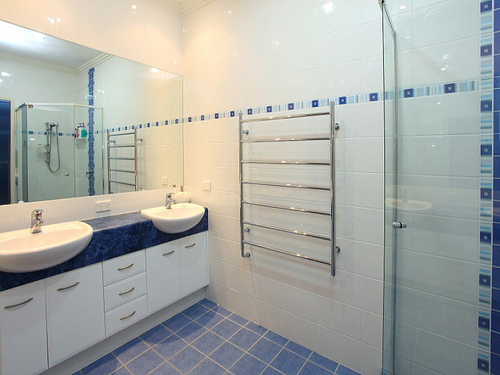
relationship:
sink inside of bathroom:
[142, 201, 205, 232] [1, 0, 498, 375]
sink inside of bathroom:
[1, 221, 94, 272] [1, 0, 498, 375]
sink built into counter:
[0, 221, 94, 272] [1, 204, 209, 296]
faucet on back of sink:
[165, 191, 177, 210] [142, 201, 205, 232]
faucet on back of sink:
[27, 206, 46, 235] [1, 221, 94, 272]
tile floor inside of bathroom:
[67, 297, 375, 374] [1, 0, 498, 375]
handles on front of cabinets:
[4, 241, 196, 320] [1, 231, 208, 374]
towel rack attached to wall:
[235, 100, 341, 278] [183, 0, 499, 373]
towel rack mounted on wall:
[235, 100, 341, 278] [183, 0, 499, 373]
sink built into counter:
[142, 201, 205, 232] [1, 204, 209, 296]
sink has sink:
[142, 201, 205, 232] [137, 201, 204, 232]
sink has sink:
[1, 221, 94, 272] [0, 221, 94, 272]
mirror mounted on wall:
[0, 20, 184, 208] [0, 0, 182, 81]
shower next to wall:
[379, 1, 498, 374] [183, 0, 499, 373]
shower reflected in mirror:
[379, 1, 498, 374] [0, 20, 184, 208]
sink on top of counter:
[0, 221, 94, 272] [1, 204, 209, 296]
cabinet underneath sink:
[146, 231, 208, 316] [142, 201, 205, 232]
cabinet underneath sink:
[2, 262, 106, 371] [1, 221, 94, 272]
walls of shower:
[382, 2, 499, 373] [379, 1, 498, 374]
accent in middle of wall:
[181, 77, 478, 125] [183, 0, 499, 373]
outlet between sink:
[95, 198, 112, 214] [0, 221, 94, 272]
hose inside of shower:
[47, 126, 63, 173] [379, 1, 498, 374]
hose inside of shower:
[47, 126, 63, 173] [15, 102, 105, 200]